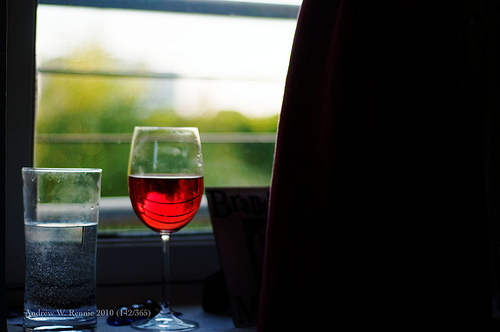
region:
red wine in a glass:
[114, 117, 242, 257]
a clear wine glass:
[120, 101, 223, 330]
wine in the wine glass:
[113, 172, 220, 227]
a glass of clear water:
[7, 152, 117, 326]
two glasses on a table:
[5, 115, 243, 324]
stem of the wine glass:
[135, 230, 202, 324]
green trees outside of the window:
[69, 51, 161, 141]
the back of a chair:
[234, 21, 498, 313]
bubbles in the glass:
[20, 240, 97, 309]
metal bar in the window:
[37, 48, 259, 100]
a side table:
[3, 278, 237, 321]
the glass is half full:
[119, 116, 213, 330]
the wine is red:
[127, 172, 191, 224]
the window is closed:
[29, 59, 268, 246]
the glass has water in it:
[16, 162, 106, 326]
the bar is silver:
[102, 196, 134, 220]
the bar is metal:
[101, 198, 134, 219]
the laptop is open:
[207, 178, 257, 258]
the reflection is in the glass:
[147, 196, 186, 216]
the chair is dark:
[315, 69, 466, 238]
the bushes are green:
[78, 108, 124, 127]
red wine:
[117, 144, 188, 245]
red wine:
[118, 122, 219, 287]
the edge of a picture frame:
[209, 188, 263, 307]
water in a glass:
[29, 222, 89, 299]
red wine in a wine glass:
[128, 165, 198, 226]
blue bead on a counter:
[116, 300, 147, 320]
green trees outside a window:
[60, 82, 142, 125]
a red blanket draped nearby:
[275, 11, 468, 330]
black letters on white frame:
[212, 180, 256, 215]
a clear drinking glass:
[24, 170, 81, 208]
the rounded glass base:
[129, 315, 189, 329]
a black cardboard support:
[203, 270, 226, 314]